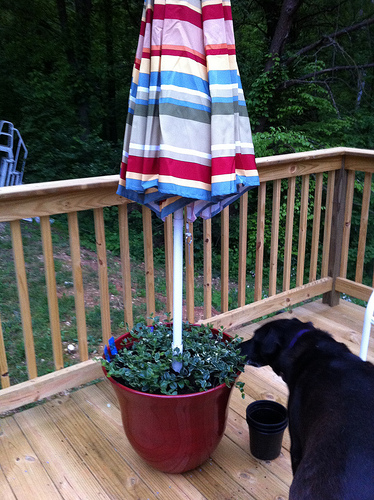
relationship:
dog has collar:
[240, 319, 371, 499] [275, 325, 330, 379]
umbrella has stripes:
[116, 1, 262, 222] [127, 11, 242, 182]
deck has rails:
[4, 149, 372, 495] [0, 147, 371, 407]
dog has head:
[240, 319, 371, 499] [236, 319, 314, 374]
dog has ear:
[240, 319, 371, 499] [256, 327, 286, 360]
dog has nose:
[240, 319, 371, 499] [233, 336, 254, 368]